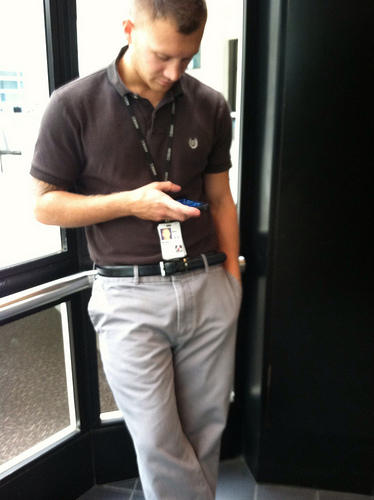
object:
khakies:
[89, 265, 246, 499]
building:
[0, 0, 372, 499]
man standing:
[30, 0, 249, 497]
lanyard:
[154, 219, 185, 263]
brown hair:
[130, 0, 207, 34]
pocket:
[221, 276, 244, 324]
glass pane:
[0, 0, 246, 482]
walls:
[240, 6, 373, 498]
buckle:
[157, 255, 193, 278]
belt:
[95, 248, 229, 275]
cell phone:
[175, 196, 208, 213]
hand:
[134, 177, 198, 221]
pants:
[87, 248, 249, 499]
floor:
[60, 448, 373, 498]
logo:
[186, 136, 199, 147]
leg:
[94, 297, 211, 499]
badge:
[156, 221, 186, 259]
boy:
[27, 0, 244, 497]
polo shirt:
[27, 42, 233, 268]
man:
[32, 0, 241, 498]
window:
[0, 1, 267, 489]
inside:
[0, 1, 373, 499]